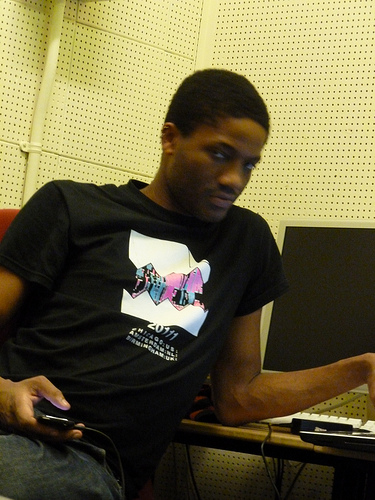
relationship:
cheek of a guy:
[168, 159, 202, 206] [0, 68, 374, 499]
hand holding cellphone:
[9, 374, 85, 439] [33, 398, 76, 428]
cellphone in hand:
[33, 398, 76, 428] [9, 367, 94, 439]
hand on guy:
[9, 367, 94, 439] [0, 68, 374, 499]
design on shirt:
[119, 227, 215, 337] [0, 178, 290, 499]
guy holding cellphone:
[0, 68, 374, 499] [31, 400, 76, 428]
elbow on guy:
[209, 355, 290, 427] [0, 68, 374, 499]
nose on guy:
[218, 157, 245, 193] [0, 68, 374, 499]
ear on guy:
[156, 111, 190, 160] [0, 68, 374, 499]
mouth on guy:
[206, 187, 235, 209] [0, 68, 374, 499]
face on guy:
[164, 120, 266, 221] [0, 68, 374, 499]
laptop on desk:
[260, 215, 374, 451] [217, 322, 370, 480]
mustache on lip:
[212, 185, 235, 194] [209, 189, 234, 209]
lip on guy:
[209, 189, 234, 209] [0, 68, 374, 499]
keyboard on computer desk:
[290, 410, 375, 432] [171, 418, 374, 496]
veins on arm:
[228, 380, 285, 409] [209, 207, 374, 426]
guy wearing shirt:
[0, 68, 374, 499] [1, 168, 284, 449]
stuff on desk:
[299, 401, 373, 447] [174, 416, 373, 499]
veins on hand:
[228, 389, 280, 410] [221, 355, 373, 412]